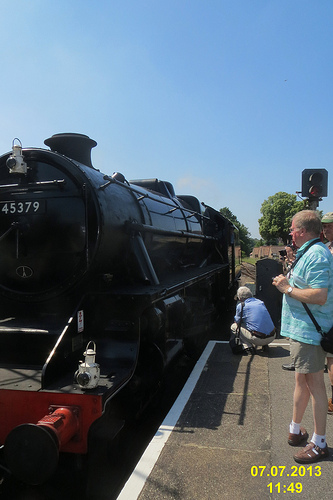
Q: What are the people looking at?
A: Train.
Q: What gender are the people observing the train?
A: Male.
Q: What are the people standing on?
A: Platform.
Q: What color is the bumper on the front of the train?
A: Red.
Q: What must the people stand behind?
A: White boundary line.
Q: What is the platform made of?
A: Concrete.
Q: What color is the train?
A: Black.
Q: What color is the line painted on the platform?
A: White.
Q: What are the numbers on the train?
A: 45379.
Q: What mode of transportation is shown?
A: Train.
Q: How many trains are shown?
A: 1.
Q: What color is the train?
A: Black.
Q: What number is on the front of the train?
A: 45379.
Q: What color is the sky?
A: Blue.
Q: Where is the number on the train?
A: Front.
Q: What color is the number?
A: White.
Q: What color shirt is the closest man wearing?
A: Blue.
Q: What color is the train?
A: Black.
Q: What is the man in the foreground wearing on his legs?
A: Shorts.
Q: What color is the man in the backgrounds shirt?
A: Blue.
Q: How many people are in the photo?
A: Two.